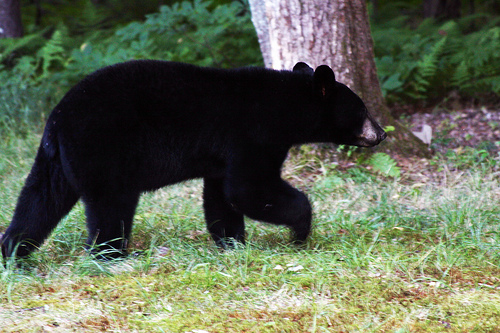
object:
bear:
[0, 60, 389, 270]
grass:
[0, 127, 499, 332]